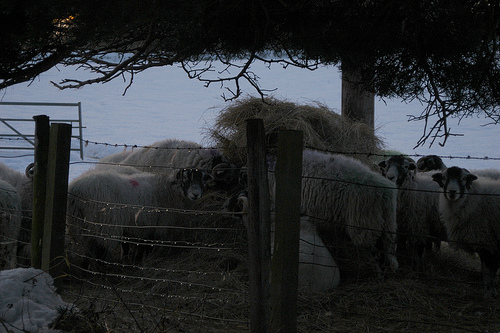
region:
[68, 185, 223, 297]
long barbed wire fence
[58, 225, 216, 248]
barbs on a wire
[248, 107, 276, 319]
wooden fence post on ground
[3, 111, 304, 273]
wooden and metal fence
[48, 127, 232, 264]
sheep standing together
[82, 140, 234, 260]
sheep on other side of fence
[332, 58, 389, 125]
brown post of tree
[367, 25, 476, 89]
green leaves from tree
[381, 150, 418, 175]
black and white head of sheep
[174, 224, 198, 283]
There is a silver fence here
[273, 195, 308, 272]
There is a fence post that is here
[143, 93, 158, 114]
There is light blue water here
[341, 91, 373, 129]
There is a light brown trunk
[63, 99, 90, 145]
There is a silver gate here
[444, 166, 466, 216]
There is a sheep that is black and white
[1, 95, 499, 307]
a herd of sheep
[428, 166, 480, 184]
two black ears on the sides of the head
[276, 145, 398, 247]
fluffy white hair on the body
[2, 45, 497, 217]
white snow on the ground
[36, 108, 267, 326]
wires running between the two posts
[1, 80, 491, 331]
sheep behind a fence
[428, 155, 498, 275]
black head on a white body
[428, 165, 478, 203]
head is turned to the side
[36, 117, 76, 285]
wooden post on the fence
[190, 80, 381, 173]
a pile of hay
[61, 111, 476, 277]
several sheep inside of a pen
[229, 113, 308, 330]
brown wood post of the fence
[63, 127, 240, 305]
brabed wire of the fence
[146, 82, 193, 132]
clear blue skies over the field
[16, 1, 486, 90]
tree growing inside of the pen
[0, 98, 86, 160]
metal gate of the fence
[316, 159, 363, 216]
white fleece of the sheep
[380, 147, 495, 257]
two sheep looking at the camera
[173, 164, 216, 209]
black and white face of the sheep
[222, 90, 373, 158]
a stack of hay inside the pen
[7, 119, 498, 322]
A herd of sheep in a sheep pen